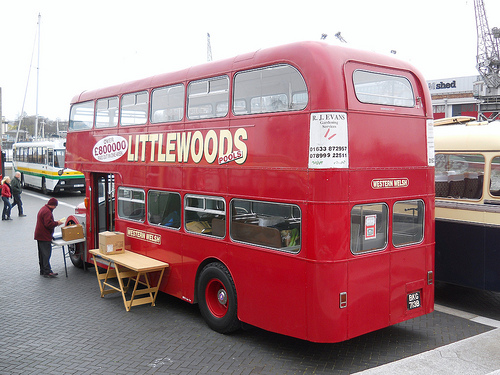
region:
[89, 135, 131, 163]
Round red and white sign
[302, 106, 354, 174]
Square red, white, and black sign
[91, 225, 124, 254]
Cardboard box on the table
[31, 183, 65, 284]
Person standing in front of a box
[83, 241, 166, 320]
Wooden folding table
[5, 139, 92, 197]
White bus with yellow and green lines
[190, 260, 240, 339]
Red and black bus wheel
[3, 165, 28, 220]
Two people walking in the background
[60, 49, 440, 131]
Windows on the top of the bus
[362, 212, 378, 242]
Sign on the bus window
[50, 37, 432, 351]
a double decker bus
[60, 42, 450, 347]
the bus is red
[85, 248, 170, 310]
small wooden table next to the bus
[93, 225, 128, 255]
cardboard box on top of the wooden table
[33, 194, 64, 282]
man wearing a dark red coat and matching hat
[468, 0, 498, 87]
red crane in the background behind the bus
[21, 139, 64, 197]
white bus with a yellow and green stripe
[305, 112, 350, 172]
white advertisement on the red bus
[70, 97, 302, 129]
windows to the top level of the bus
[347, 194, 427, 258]
two windows on the back of the bus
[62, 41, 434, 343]
Red double decker bus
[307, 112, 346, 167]
Small advertisement on bus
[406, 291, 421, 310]
Black and white license plate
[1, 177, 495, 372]
Herringbone patterned street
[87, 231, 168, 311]
Small table supporting a single box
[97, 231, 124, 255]
Cardboard box rest on table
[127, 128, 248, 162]
Large pool advertisment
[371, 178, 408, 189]
Logo of bus' maker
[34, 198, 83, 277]
Man dressed in red sets up table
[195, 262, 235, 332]
Wheel of the bus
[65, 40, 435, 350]
a red double decker bus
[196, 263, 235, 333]
a bus' rear tire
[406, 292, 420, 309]
a black and white license plate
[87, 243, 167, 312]
a folding brown table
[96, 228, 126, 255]
a brown cardboard box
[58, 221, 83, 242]
a brown cardboard box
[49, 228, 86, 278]
a folding white table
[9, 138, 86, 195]
a white yellow and green bus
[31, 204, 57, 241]
a red winter coat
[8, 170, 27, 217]
a pedestrian walking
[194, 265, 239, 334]
a wheel of a bus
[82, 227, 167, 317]
a table with a box on top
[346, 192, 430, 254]
the rear window of a bus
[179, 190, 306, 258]
windows in the side of a bus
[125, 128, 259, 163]
white letters on a bus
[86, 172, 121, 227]
the door of a bus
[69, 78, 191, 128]
the windows on a bus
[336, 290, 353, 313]
a tail light of a bus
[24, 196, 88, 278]
a person standing by a table